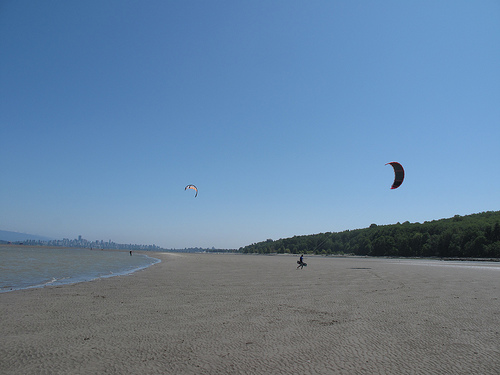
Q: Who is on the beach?
A: A person flying a kite.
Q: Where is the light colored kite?
A: On the left in the distance.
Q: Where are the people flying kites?
A: On a beach.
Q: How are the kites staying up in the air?
A: Wind.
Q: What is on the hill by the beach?
A: Trees.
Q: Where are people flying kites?
A: On the beach.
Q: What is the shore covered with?
A: Sand.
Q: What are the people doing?
A: Flying kites.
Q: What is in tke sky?
A: Two kites.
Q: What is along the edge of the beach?
A: A row of trees.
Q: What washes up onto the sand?
A: The waves in the water.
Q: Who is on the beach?
A: Two people.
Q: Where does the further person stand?
A: In the water.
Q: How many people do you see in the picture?
A: 2.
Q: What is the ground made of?
A: Sand.